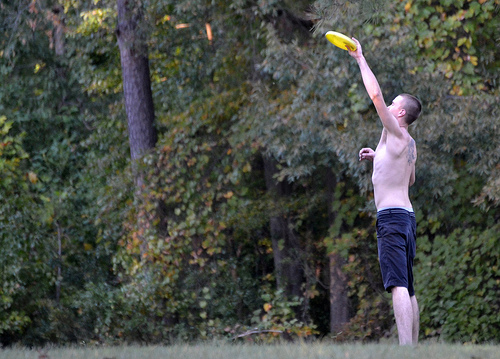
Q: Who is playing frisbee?
A: The man in the blue shorts.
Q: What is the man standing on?
A: Grass.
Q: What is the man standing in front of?
A: Trees.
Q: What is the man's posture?
A: He is standing.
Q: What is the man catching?
A: A frisbee.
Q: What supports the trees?
A: Their trunks.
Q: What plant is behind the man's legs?
A: A green bush.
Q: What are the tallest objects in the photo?
A: The trees.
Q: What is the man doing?
A: Catching a frisbee.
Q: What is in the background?
A: Trees.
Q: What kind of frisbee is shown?
A: A round yellow plastic frisbee.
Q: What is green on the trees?
A: Leaves.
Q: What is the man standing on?
A: Grass.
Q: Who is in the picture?
A: A man.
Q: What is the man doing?
A: Catching a frisbee.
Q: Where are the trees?
A: Behind the man.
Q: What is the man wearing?
A: Shorts.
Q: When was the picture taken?
A: At daytime.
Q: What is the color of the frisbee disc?
A: Yellow.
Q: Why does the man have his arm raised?
A: To catch the disc.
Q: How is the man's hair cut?
A: Short.